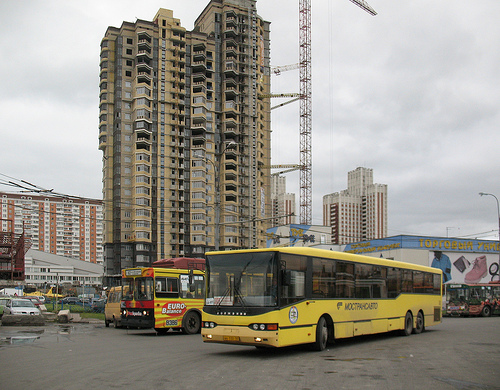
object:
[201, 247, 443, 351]
bus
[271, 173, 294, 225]
building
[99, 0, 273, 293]
building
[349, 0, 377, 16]
crane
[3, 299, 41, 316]
car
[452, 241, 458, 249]
writing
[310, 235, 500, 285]
building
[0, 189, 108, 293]
building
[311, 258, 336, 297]
window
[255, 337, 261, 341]
light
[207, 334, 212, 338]
light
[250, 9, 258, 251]
ladder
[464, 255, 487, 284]
shoe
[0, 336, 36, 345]
water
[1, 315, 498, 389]
road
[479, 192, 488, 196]
light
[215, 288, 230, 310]
wiper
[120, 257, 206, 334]
bus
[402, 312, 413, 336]
wheel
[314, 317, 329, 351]
wheel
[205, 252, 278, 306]
windshield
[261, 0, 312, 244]
structure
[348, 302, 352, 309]
writing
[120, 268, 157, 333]
front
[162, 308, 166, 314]
writing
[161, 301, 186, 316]
decal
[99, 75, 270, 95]
story